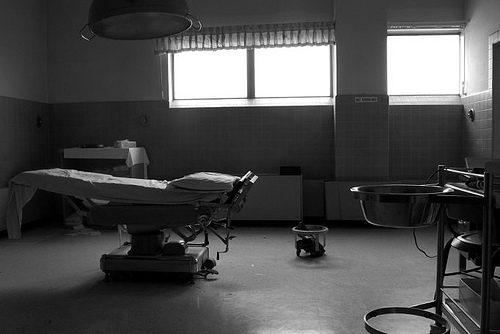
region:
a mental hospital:
[56, 71, 407, 320]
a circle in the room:
[297, 184, 354, 278]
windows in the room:
[115, 65, 380, 111]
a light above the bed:
[45, 11, 228, 74]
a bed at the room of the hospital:
[24, 136, 270, 264]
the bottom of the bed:
[88, 204, 266, 309]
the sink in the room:
[310, 122, 497, 290]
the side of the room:
[236, 99, 409, 171]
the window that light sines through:
[375, 24, 478, 112]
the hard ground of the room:
[249, 272, 356, 331]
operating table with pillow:
[6, 135, 258, 278]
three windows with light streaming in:
[165, 37, 455, 94]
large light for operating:
[65, 0, 197, 40]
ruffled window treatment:
[160, 15, 335, 50]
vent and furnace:
[255, 160, 305, 221]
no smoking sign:
[350, 85, 381, 110]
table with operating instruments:
[57, 127, 147, 232]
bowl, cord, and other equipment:
[350, 131, 495, 328]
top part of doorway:
[485, 20, 495, 170]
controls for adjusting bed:
[90, 202, 216, 272]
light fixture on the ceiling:
[76, 4, 214, 54]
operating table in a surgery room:
[13, 161, 275, 289]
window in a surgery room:
[146, 22, 339, 122]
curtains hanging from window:
[154, 23, 336, 61]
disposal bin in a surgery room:
[339, 173, 457, 332]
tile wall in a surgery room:
[180, 112, 330, 157]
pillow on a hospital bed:
[167, 167, 243, 194]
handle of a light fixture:
[77, 19, 98, 49]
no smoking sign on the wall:
[344, 94, 392, 106]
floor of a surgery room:
[11, 284, 356, 326]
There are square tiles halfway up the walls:
[43, 83, 479, 181]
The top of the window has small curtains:
[153, 23, 353, 111]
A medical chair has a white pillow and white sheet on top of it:
[21, 155, 301, 303]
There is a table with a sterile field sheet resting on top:
[51, 125, 167, 229]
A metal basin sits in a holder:
[334, 165, 488, 331]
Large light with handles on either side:
[73, 5, 218, 60]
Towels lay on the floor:
[51, 196, 100, 246]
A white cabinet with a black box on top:
[176, 163, 308, 230]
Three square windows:
[141, 19, 479, 112]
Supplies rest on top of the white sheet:
[66, 126, 141, 158]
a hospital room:
[1, 24, 491, 331]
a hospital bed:
[18, 131, 260, 283]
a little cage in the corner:
[289, 203, 344, 268]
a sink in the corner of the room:
[341, 159, 477, 274]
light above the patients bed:
[82, 4, 227, 61]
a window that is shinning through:
[150, 18, 362, 118]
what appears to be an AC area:
[229, 166, 315, 221]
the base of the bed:
[93, 238, 263, 288]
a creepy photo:
[23, 1, 485, 325]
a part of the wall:
[338, 21, 395, 95]